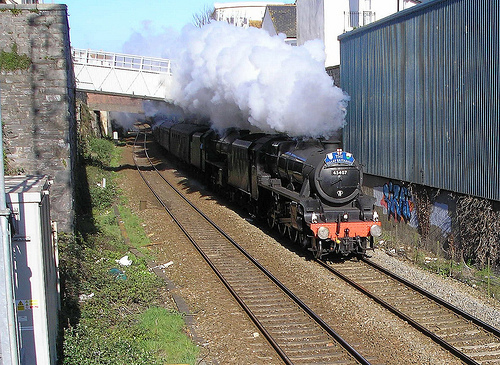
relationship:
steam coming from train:
[140, 28, 353, 139] [153, 112, 375, 245]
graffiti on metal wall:
[379, 179, 423, 221] [342, 20, 499, 192]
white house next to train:
[296, 1, 396, 69] [153, 112, 375, 245]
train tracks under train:
[132, 135, 494, 363] [153, 112, 375, 245]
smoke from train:
[140, 28, 353, 139] [153, 112, 375, 245]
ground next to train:
[90, 135, 211, 349] [153, 112, 375, 245]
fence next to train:
[0, 7, 117, 216] [153, 112, 375, 245]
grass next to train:
[78, 138, 172, 361] [153, 112, 375, 245]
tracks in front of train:
[209, 251, 492, 363] [153, 112, 375, 245]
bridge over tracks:
[71, 52, 185, 100] [209, 251, 492, 363]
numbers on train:
[331, 166, 354, 178] [153, 112, 375, 245]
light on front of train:
[318, 227, 329, 238] [153, 112, 375, 245]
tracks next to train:
[209, 251, 492, 363] [153, 112, 375, 245]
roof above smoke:
[269, 3, 296, 41] [140, 28, 353, 139]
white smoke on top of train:
[140, 28, 353, 139] [153, 112, 375, 245]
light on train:
[369, 224, 384, 238] [153, 112, 375, 245]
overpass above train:
[71, 52, 185, 100] [153, 112, 375, 245]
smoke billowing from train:
[140, 28, 353, 139] [153, 112, 375, 245]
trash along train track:
[100, 248, 136, 287] [132, 135, 494, 363]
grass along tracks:
[78, 138, 172, 361] [209, 251, 492, 363]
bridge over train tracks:
[71, 52, 185, 100] [132, 135, 494, 363]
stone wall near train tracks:
[3, 5, 75, 229] [132, 135, 494, 363]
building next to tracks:
[221, 2, 382, 64] [209, 251, 492, 363]